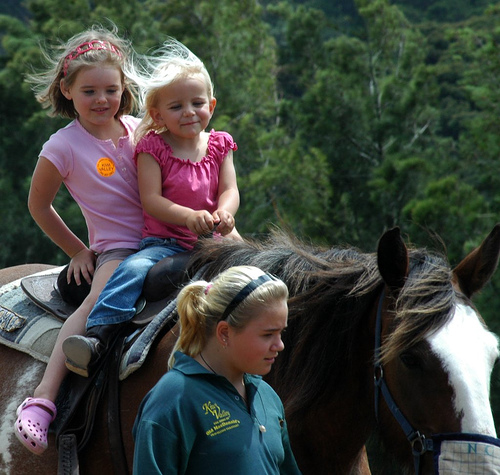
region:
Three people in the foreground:
[6, 5, 346, 470]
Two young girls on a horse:
[7, 22, 497, 457]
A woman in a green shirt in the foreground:
[115, 262, 318, 472]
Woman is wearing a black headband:
[198, 260, 293, 335]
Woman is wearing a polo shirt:
[125, 353, 311, 473]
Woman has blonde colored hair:
[162, 255, 292, 365]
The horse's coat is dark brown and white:
[3, 227, 496, 472]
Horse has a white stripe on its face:
[403, 275, 496, 440]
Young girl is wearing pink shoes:
[8, 385, 63, 460]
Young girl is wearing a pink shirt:
[33, 107, 147, 251]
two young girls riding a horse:
[0, 22, 497, 472]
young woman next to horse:
[0, 225, 496, 470]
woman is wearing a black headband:
[218, 266, 282, 326]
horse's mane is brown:
[193, 222, 460, 368]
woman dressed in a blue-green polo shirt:
[131, 347, 301, 474]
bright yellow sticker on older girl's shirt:
[95, 156, 115, 178]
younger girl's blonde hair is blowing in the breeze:
[123, 36, 215, 139]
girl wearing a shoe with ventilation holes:
[15, 383, 58, 455]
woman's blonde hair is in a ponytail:
[173, 264, 285, 359]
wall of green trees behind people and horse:
[2, 1, 499, 472]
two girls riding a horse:
[7, 30, 494, 471]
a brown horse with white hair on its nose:
[2, 226, 496, 466]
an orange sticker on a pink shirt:
[97, 156, 119, 177]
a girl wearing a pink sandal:
[13, 398, 60, 451]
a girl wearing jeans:
[88, 236, 187, 371]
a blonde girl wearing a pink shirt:
[138, 43, 238, 243]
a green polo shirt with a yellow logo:
[137, 358, 301, 471]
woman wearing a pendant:
[198, 347, 271, 437]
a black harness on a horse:
[368, 274, 495, 470]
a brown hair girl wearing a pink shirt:
[28, 29, 147, 249]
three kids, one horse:
[0, 12, 498, 473]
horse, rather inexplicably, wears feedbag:
[366, 268, 498, 472]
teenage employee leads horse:
[117, 261, 317, 473]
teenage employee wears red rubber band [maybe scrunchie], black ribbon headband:
[195, 269, 280, 326]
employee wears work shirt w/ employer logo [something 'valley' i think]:
[193, 395, 243, 445]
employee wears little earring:
[215, 332, 230, 353]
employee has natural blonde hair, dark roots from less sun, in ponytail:
[165, 257, 292, 376]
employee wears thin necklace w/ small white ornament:
[198, 348, 277, 438]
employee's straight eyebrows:
[258, 325, 291, 335]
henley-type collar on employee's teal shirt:
[166, 347, 271, 428]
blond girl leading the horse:
[131, 262, 321, 473]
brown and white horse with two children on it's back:
[0, 259, 498, 474]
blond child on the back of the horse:
[63, 51, 273, 393]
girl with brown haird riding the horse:
[28, 18, 158, 448]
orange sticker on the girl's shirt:
[91, 157, 118, 179]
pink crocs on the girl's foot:
[10, 391, 62, 460]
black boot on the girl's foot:
[64, 313, 119, 385]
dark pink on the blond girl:
[136, 129, 246, 252]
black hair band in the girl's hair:
[209, 266, 281, 336]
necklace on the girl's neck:
[191, 349, 274, 439]